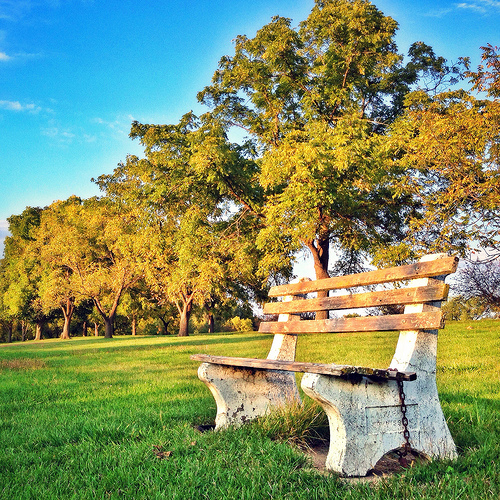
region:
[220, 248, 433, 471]
The bench in the park.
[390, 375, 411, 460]
Chain hanging from the bench.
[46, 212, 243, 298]
The trees are big and green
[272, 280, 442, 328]
Top of bench is wood.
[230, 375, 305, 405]
Paint peeling off the bench.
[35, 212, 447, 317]
Trees behind the bench.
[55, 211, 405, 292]
Trees in the park.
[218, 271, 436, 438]
The bench is very old.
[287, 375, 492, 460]
The legs of bench is concrete.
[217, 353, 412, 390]
The seat of bench is wood.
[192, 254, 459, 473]
a wood and concrete bench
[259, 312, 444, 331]
a brown wood slat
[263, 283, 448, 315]
a brown wood slat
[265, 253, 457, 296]
a brown wood slat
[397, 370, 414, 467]
a rusted metal chain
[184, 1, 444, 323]
large green tree in distance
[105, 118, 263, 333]
large green tree in distance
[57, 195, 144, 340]
large green tree in distance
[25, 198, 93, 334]
large green tree in distance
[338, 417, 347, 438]
edge of a bench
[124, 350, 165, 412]
part of a filed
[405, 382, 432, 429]
part of a bench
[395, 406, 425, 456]
part of a chian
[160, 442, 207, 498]
part of a ground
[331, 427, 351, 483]
edge of a bench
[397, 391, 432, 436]
part of a chain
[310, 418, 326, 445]
part of a grass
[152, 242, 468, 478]
a park bench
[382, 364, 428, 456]
a chain on the bench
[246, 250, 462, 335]
the wooden back of the bench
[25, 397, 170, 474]
green grass in front of the bench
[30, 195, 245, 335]
trees in the background with colorful leaves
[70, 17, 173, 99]
blue sky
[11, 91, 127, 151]
some clouds in the sky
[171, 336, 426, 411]
the wooden seat of the bench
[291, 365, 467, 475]
the cement base of the bench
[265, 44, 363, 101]
leaves on the trees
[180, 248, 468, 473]
bench in the middle of a park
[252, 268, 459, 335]
wooden slats of back of park bench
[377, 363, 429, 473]
bench chained down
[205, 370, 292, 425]
cement support of a park bench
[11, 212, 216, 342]
tall trees in a park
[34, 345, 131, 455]
grassy field of a park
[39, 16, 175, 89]
bright blue skies on a sunny day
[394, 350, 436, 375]
crack in support of park bench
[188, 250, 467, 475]
wood and concrete park bench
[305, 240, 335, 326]
large tree trunk